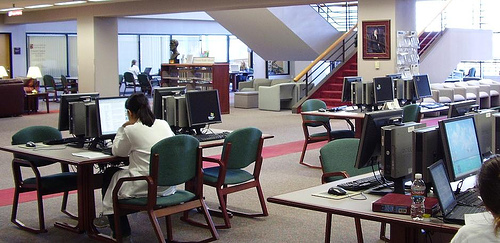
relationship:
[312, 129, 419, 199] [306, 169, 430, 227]
chair at desk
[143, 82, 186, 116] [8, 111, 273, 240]
computer on desk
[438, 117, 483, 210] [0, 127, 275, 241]
computer sitting on desk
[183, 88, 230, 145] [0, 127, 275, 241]
computer sitting on desk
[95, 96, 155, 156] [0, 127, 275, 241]
computer sitting on desk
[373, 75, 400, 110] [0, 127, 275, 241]
computer sitting on desk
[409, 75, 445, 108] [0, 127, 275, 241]
computer sitting on desk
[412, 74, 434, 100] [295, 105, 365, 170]
computer on desk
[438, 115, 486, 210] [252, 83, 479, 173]
computer on desk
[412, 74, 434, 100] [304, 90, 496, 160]
computer on desk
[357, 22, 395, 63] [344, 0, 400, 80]
photo wall on wall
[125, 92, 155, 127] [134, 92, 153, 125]
hair in a ponytail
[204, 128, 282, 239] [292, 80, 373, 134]
chair at a desk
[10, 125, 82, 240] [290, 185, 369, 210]
chair at a desk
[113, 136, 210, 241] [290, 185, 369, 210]
chair at a desk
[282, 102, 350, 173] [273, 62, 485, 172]
chair at a desk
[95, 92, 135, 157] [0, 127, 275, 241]
computer on a desk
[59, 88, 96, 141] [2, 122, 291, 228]
computer on a desk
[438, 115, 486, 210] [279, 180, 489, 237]
computer on a desk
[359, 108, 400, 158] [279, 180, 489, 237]
computer on a desk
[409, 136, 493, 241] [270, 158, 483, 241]
computer on a desk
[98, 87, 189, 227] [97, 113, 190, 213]
woman in a coat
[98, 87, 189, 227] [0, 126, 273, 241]
woman sitting at computer desk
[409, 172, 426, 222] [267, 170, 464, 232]
bottle on desk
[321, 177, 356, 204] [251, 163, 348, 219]
computer mouse on desk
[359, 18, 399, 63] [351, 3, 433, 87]
picture on wall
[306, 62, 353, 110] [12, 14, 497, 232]
staircase in computer lap